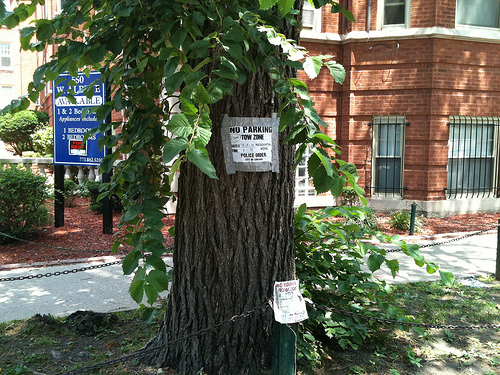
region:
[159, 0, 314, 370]
Trunk of a tree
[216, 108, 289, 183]
No parking sign on a tree trunk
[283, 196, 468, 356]
Bush on right side of tree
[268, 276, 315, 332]
Sign on a tree is white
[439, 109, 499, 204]
Window of a building is fenced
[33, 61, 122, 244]
Street sign is blue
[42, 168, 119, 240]
Black sticks hold street sign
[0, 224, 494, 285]
Tree is fenced with a chain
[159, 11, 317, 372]
Tree has dark brown bark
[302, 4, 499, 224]
Build is made of brick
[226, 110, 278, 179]
no parking sign taped to tree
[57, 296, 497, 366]
chain and post along street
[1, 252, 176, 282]
chain along sidewalk behind tree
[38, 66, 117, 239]
for sale sign in front of building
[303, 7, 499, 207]
part of red brick building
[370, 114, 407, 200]
iron bars on window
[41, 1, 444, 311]
green foliage growing on tree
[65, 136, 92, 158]
for rent sign on large blue sign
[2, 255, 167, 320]
sidewalk behind tree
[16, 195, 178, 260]
red gravel in front of building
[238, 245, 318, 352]
square white sign on tree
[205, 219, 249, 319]
black grooves in tree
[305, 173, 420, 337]
bushy leaves on tree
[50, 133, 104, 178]
red words on sign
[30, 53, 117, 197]
blue and white sign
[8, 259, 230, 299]
long link black chain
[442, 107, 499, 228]
burglar bars on windows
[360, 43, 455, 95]
red and white bricks on wall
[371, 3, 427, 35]
white windows in building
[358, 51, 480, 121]
lines in building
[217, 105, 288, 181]
a sign mounted by duct tape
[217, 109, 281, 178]
a sign being held up by duct tape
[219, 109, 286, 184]
a no parking sign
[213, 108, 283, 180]
a no parking sign on a tree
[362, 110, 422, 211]
a window with bars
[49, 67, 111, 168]
a real estate sign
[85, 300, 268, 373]
a chain attached to a tree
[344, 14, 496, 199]
shade on a brick wall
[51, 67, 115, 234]
a sign on two posts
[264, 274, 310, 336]
a low hanging poster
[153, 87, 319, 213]
sign with grey tape attached to tree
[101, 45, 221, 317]
branches growing down trunk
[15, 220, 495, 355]
fence made with black chains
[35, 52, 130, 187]
blue and white sign about housing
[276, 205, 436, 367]
branches growing by side of tree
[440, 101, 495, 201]
metal bars covering a window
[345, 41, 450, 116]
brickwork with rows of indentations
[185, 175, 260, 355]
rough texture of tree trunk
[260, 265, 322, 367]
small sign around lower part of tree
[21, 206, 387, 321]
tree growing next to sidewalk